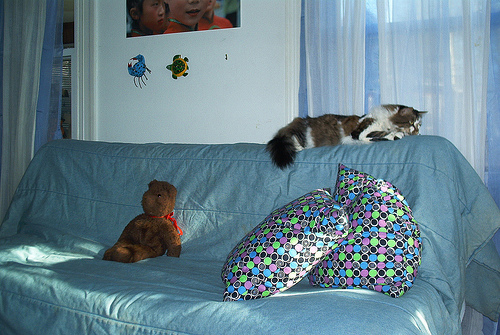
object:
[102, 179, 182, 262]
teddy bear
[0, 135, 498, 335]
couch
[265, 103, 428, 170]
cat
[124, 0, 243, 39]
picture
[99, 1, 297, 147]
wall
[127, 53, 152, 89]
crab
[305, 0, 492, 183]
curtains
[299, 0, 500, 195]
window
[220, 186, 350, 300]
pillow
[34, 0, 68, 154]
curtain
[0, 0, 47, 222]
curtain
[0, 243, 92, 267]
sunlight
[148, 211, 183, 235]
ribbon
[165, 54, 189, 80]
turtle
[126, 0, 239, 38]
kids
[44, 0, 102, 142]
window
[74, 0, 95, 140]
window trim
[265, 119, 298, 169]
tail